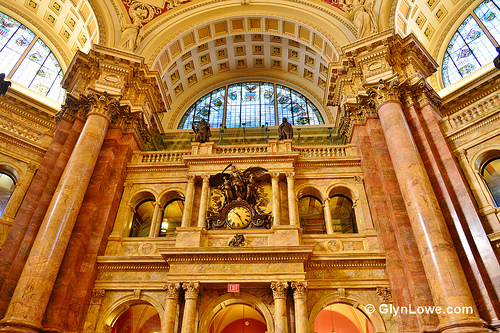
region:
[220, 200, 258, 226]
A clock in the photo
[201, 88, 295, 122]
Window panes in the photo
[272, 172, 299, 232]
Pillars in the photo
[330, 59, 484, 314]
A pillar in the building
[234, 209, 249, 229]
Arms of a clock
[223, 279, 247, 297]
A signage in the building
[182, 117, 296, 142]
Statues in the photo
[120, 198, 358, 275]
Balcony in the photo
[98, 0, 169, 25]
Roof of a building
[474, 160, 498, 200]
Window in the building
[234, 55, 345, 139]
This is a window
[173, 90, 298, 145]
The window is stained glass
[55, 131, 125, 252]
This is a column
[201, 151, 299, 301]
This is a clock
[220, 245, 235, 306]
This is a sign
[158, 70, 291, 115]
The ceiling is yellow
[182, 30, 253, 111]
This is yellow molding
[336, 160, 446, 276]
The column is marble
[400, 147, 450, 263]
The marble is red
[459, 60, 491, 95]
The window is colorful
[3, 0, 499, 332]
a building with a dome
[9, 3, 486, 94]
a dome on top a building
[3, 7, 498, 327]
the inside of an old building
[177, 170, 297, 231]
a clock in middle of columns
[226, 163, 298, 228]
two columns on right side of clock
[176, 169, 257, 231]
two columns on left side of clock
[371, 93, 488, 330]
a big brown column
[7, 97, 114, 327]
a big brown column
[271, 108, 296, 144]
a statue on top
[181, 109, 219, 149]
a statue on top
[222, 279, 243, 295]
a red exit sign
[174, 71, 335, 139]
an arched window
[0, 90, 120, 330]
a tall pillar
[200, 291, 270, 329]
an arched doorway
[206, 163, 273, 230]
a decorative clock on a balcony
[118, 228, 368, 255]
a carved balcony rail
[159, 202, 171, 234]
a light hanging from a ceiling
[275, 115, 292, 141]
a statue on top of a railing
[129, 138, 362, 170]
railing underneath a window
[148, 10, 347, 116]
a white and gold arched decorative ceiling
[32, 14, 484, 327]
the hallway of a building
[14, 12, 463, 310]
the entrance of a large structure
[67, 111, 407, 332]
this entrance way is very colorful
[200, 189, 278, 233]
a clock high up on the wall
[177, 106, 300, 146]
two statues high above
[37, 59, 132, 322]
a large pillar in the hallway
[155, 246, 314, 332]
an exit point in the entrance way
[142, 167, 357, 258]
a balcony on the second floor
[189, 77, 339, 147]
a window high up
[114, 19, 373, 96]
an arched ceiling above